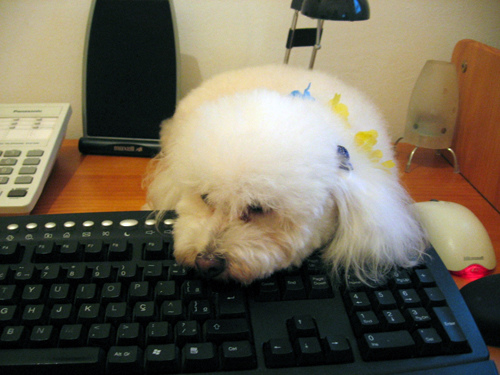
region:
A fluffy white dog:
[133, 60, 440, 274]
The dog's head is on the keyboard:
[139, 113, 420, 266]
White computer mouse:
[421, 178, 489, 281]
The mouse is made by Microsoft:
[451, 243, 499, 268]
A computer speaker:
[69, 6, 195, 156]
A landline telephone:
[5, 81, 67, 210]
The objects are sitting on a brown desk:
[0, 28, 496, 270]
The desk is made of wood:
[17, 37, 497, 214]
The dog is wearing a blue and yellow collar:
[278, 78, 413, 168]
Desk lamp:
[279, 0, 365, 64]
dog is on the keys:
[114, 43, 431, 328]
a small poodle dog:
[88, 33, 407, 323]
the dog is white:
[91, 48, 398, 296]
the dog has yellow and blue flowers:
[126, 17, 486, 299]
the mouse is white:
[405, 179, 491, 291]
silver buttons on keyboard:
[6, 199, 167, 256]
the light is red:
[404, 183, 493, 288]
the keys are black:
[39, 143, 305, 372]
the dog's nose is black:
[149, 40, 403, 290]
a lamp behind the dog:
[276, 3, 402, 153]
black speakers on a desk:
[80, 29, 169, 154]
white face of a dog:
[159, 146, 291, 276]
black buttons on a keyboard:
[79, 272, 147, 358]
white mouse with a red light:
[411, 178, 496, 307]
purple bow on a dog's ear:
[328, 137, 363, 180]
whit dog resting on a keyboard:
[139, 49, 435, 311]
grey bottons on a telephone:
[8, 152, 29, 191]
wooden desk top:
[55, 156, 127, 221]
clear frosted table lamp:
[392, 54, 466, 191]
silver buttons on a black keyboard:
[44, 219, 131, 234]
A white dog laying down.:
[139, 63, 427, 283]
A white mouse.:
[412, 199, 495, 274]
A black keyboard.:
[2, 214, 490, 370]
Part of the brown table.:
[72, 176, 117, 196]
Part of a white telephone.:
[0, 98, 73, 212]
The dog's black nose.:
[193, 248, 225, 277]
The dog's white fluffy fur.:
[231, 123, 291, 160]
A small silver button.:
[6, 219, 18, 231]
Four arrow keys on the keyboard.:
[264, 312, 354, 369]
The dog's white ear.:
[328, 156, 430, 285]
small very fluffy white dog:
[140, 64, 430, 286]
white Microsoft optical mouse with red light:
[408, 199, 495, 277]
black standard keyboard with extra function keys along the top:
[0, 210, 497, 374]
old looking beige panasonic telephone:
[0, 102, 71, 212]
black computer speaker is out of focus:
[78, 0, 177, 157]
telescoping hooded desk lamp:
[283, 0, 370, 70]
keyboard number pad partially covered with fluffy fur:
[336, 256, 471, 358]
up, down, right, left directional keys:
[263, 315, 353, 367]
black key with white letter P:
[126, 280, 148, 300]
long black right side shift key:
[201, 316, 251, 338]